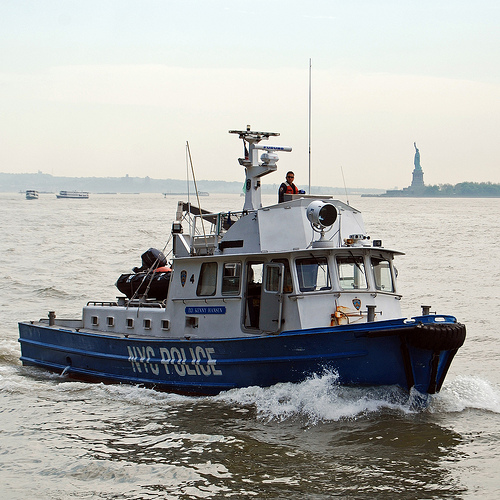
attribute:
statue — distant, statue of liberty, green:
[412, 141, 422, 171]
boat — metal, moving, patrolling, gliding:
[16, 126, 466, 402]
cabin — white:
[164, 197, 405, 341]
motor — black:
[132, 247, 168, 273]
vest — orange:
[282, 180, 301, 198]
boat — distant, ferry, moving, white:
[56, 190, 89, 199]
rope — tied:
[142, 233, 170, 305]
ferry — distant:
[26, 190, 40, 199]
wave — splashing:
[218, 359, 500, 439]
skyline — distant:
[1, 174, 392, 196]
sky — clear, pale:
[0, 2, 500, 190]